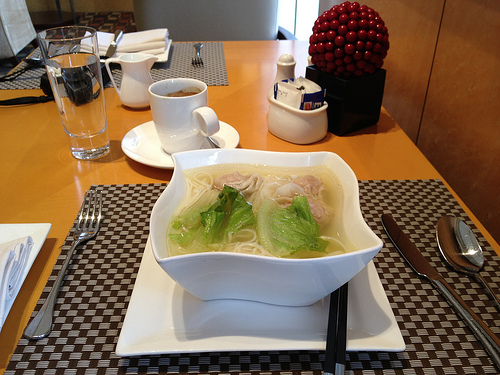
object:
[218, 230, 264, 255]
noodles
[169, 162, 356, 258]
soup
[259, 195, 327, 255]
leaf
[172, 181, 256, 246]
leaf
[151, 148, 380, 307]
bowl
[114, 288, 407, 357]
plate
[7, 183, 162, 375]
placemat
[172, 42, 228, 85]
placemat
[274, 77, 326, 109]
sweetner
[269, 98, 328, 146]
container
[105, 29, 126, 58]
knife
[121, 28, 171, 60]
napkin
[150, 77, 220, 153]
cup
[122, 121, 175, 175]
saucer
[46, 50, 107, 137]
liquid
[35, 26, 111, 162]
glass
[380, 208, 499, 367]
knife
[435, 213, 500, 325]
spoon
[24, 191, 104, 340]
fork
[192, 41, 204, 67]
fork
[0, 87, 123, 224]
table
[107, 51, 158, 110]
pitcher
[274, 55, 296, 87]
salt shaker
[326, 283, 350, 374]
chopsticks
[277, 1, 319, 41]
window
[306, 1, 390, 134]
decoration